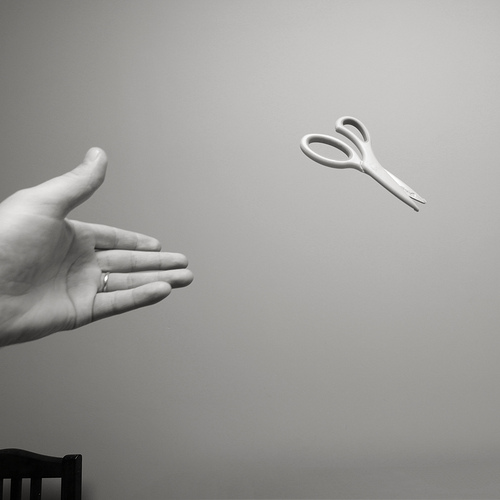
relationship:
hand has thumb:
[3, 145, 196, 351] [33, 146, 110, 218]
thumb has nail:
[33, 146, 110, 218] [86, 146, 103, 170]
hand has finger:
[3, 145, 196, 351] [66, 216, 161, 252]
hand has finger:
[3, 145, 196, 351] [99, 245, 189, 276]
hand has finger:
[3, 145, 196, 351] [99, 269, 196, 290]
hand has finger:
[3, 145, 196, 351] [96, 279, 172, 320]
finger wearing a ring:
[99, 269, 196, 290] [100, 271, 113, 292]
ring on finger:
[100, 271, 113, 292] [99, 269, 196, 290]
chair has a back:
[0, 446, 84, 499] [1, 448, 82, 499]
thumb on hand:
[33, 146, 110, 218] [3, 145, 196, 351]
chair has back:
[0, 446, 84, 499] [1, 448, 82, 499]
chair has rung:
[0, 446, 84, 499] [29, 475, 44, 499]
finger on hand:
[66, 216, 161, 252] [3, 145, 196, 351]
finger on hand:
[99, 245, 189, 276] [3, 145, 196, 351]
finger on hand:
[99, 269, 196, 290] [3, 145, 196, 351]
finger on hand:
[96, 279, 172, 320] [3, 145, 196, 351]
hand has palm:
[3, 145, 196, 351] [14, 223, 94, 326]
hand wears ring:
[3, 145, 196, 351] [100, 271, 113, 292]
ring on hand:
[100, 271, 113, 292] [3, 145, 196, 351]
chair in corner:
[0, 446, 84, 499] [1, 422, 97, 499]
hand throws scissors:
[3, 145, 196, 351] [298, 113, 428, 215]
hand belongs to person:
[3, 145, 196, 351] [3, 141, 195, 363]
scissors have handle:
[298, 113, 428, 215] [299, 132, 362, 169]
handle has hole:
[299, 132, 362, 169] [308, 138, 352, 165]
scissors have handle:
[298, 113, 428, 215] [335, 113, 375, 149]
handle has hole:
[335, 113, 375, 149] [343, 119, 370, 144]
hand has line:
[3, 145, 196, 351] [62, 252, 89, 330]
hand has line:
[3, 145, 196, 351] [90, 291, 100, 324]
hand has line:
[3, 145, 196, 351] [51, 228, 76, 280]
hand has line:
[3, 145, 196, 351] [1, 286, 39, 302]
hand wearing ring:
[3, 145, 196, 351] [100, 271, 113, 292]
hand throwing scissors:
[3, 145, 196, 351] [298, 113, 428, 215]